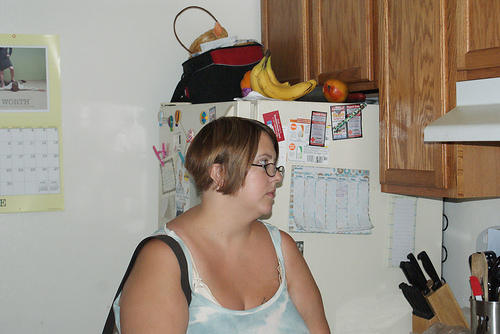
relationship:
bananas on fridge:
[241, 53, 313, 107] [163, 85, 405, 216]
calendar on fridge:
[299, 156, 391, 237] [163, 85, 405, 216]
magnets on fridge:
[159, 114, 201, 155] [163, 85, 405, 216]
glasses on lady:
[239, 166, 305, 189] [102, 117, 331, 334]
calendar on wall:
[3, 39, 91, 245] [86, 10, 152, 245]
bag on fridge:
[172, 39, 240, 93] [163, 85, 405, 216]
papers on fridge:
[162, 168, 187, 199] [163, 85, 405, 216]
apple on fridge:
[299, 75, 371, 119] [163, 85, 405, 216]